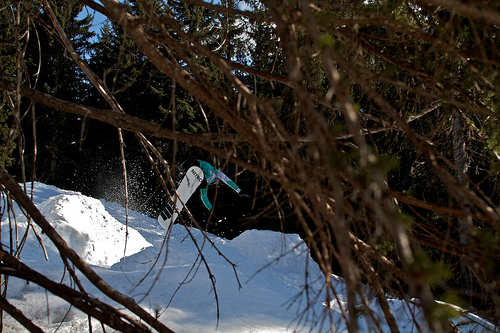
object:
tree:
[1, 2, 497, 332]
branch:
[0, 163, 175, 333]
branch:
[100, 1, 266, 155]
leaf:
[364, 153, 404, 175]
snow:
[0, 178, 495, 331]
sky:
[73, 2, 136, 84]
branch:
[331, 49, 500, 222]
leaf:
[388, 208, 416, 229]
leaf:
[313, 31, 335, 51]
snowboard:
[157, 164, 204, 228]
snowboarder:
[175, 159, 252, 216]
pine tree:
[79, 16, 123, 105]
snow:
[104, 153, 167, 231]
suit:
[196, 158, 242, 212]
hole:
[49, 306, 73, 322]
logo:
[190, 167, 204, 183]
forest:
[1, 1, 498, 324]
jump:
[14, 192, 156, 266]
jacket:
[199, 159, 241, 212]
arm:
[215, 166, 241, 193]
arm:
[201, 186, 213, 210]